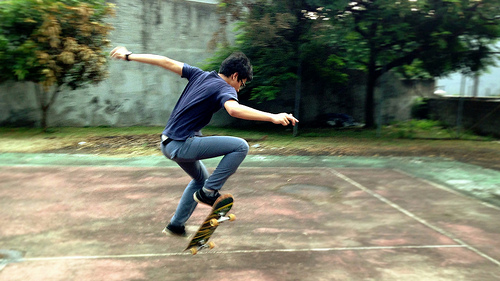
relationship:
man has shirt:
[110, 46, 300, 238] [163, 65, 239, 139]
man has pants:
[110, 46, 300, 238] [162, 136, 249, 222]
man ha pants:
[110, 46, 300, 238] [162, 136, 249, 222]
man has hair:
[110, 46, 300, 238] [218, 50, 253, 81]